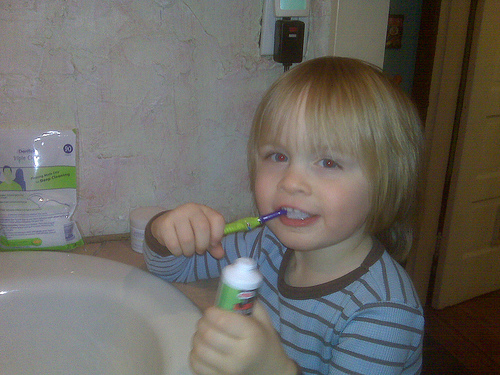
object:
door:
[431, 0, 500, 311]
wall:
[0, 0, 392, 242]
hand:
[187, 299, 298, 375]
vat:
[129, 205, 167, 254]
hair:
[245, 55, 425, 264]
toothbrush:
[223, 209, 288, 236]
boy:
[142, 55, 426, 375]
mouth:
[275, 203, 322, 227]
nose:
[277, 167, 312, 196]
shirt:
[141, 209, 425, 375]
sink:
[0, 249, 207, 375]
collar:
[276, 237, 386, 301]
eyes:
[265, 151, 343, 170]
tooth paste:
[213, 256, 264, 317]